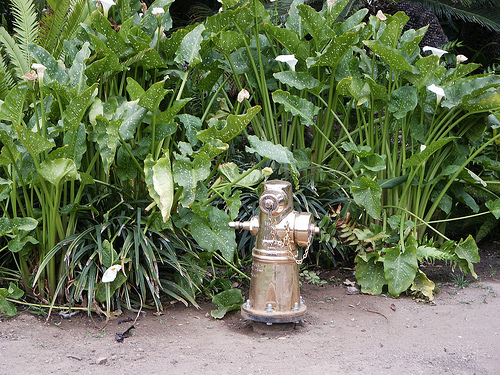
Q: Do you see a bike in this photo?
A: No, there are no bikes.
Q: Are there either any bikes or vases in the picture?
A: No, there are no bikes or vases.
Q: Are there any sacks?
A: No, there are no sacks.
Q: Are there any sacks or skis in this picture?
A: No, there are no sacks or skis.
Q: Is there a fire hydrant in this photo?
A: Yes, there is a fire hydrant.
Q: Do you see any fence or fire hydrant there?
A: Yes, there is a fire hydrant.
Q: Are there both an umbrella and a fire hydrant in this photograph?
A: No, there is a fire hydrant but no umbrellas.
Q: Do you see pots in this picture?
A: No, there are no pots.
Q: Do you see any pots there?
A: No, there are no pots.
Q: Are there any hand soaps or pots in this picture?
A: No, there are no pots or hand soaps.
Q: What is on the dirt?
A: The fire hydrant is on the dirt.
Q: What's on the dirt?
A: The fire hydrant is on the dirt.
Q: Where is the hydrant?
A: The hydrant is on the dirt.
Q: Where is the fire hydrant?
A: The hydrant is on the dirt.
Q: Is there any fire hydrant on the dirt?
A: Yes, there is a fire hydrant on the dirt.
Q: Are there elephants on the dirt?
A: No, there is a fire hydrant on the dirt.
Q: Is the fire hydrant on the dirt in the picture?
A: Yes, the fire hydrant is on the dirt.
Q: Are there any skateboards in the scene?
A: No, there are no skateboards.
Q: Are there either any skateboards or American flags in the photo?
A: No, there are no skateboards or American flags.